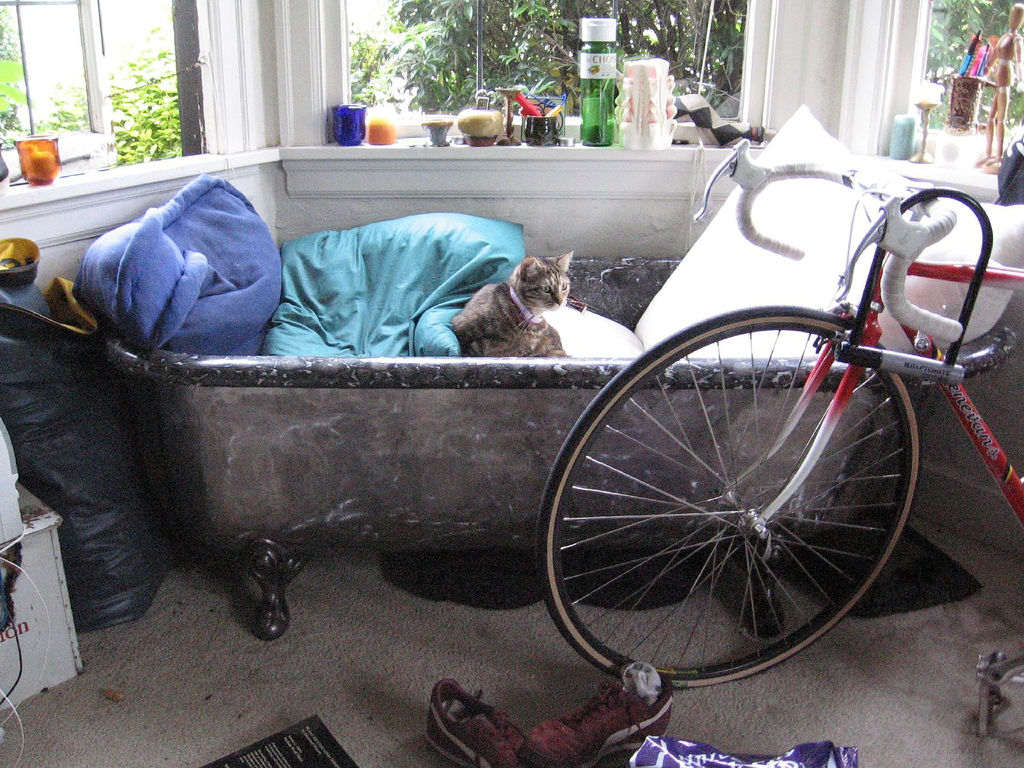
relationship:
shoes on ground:
[421, 651, 687, 764] [0, 525, 1018, 765]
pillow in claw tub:
[75, 171, 292, 362] [98, 289, 883, 665]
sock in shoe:
[620, 655, 670, 705] [518, 655, 691, 764]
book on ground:
[186, 709, 379, 764] [0, 525, 1018, 765]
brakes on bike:
[683, 134, 763, 232] [527, 135, 1022, 741]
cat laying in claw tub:
[451, 247, 592, 362] [98, 289, 883, 665]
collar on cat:
[493, 273, 554, 343] [443, 245, 595, 371]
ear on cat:
[516, 251, 547, 280] [454, 247, 591, 377]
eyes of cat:
[531, 277, 575, 297] [451, 247, 592, 362]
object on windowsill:
[320, 93, 381, 163] [277, 104, 774, 180]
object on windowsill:
[878, 98, 924, 185] [869, 136, 1012, 230]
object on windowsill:
[618, 52, 683, 159] [275, 108, 783, 191]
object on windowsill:
[506, 104, 561, 159] [292, 121, 761, 182]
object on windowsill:
[666, 93, 723, 163] [286, 119, 771, 219]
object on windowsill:
[450, 93, 509, 169] [288, 136, 773, 225]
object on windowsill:
[63, 143, 115, 193] [3, 160, 191, 236]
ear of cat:
[549, 245, 584, 274] [428, 236, 588, 375]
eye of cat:
[551, 275, 571, 299] [428, 236, 606, 383]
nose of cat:
[543, 288, 572, 308] [426, 238, 599, 364]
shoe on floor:
[398, 662, 561, 766] [130, 633, 908, 763]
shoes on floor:
[541, 651, 687, 752] [126, 621, 950, 762]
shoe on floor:
[958, 621, 1023, 766] [180, 651, 956, 766]